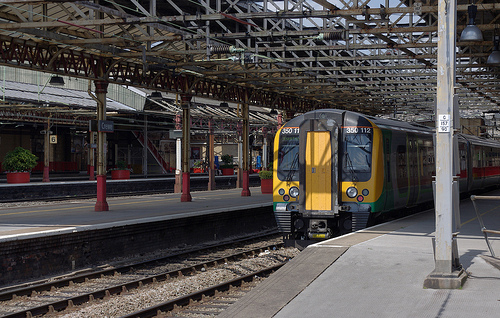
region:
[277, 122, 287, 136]
The number 3 in white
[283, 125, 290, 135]
the number 5 in white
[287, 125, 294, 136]
the number 0 in white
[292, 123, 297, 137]
the number 1 in white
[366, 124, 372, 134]
the number 2 in white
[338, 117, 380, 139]
the number 350 112 in white?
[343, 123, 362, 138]
the number 350 in white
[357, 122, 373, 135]
the number 112 in white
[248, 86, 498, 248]
A big yellow train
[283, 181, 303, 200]
a silver head light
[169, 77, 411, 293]
train with yellow nose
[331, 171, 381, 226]
red and green lights next to headlight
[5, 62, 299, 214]
metal poles with red paint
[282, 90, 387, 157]
numbers on nose of train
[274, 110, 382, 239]
two windows on nose of train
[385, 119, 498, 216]
red stripe on side of train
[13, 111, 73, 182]
sign with number 6 on it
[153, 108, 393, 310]
train on train tracks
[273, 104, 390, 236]
yellow black green on train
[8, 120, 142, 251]
plant on train platform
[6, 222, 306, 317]
two sets of metal train tacks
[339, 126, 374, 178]
a window on a train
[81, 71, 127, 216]
a steel support column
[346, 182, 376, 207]
lights on the front of a train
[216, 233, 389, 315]
a train platform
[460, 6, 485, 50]
an over head light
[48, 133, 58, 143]
the number 6 on a sign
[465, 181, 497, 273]
a metal railing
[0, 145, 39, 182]
a plant in a large pot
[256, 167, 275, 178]
a green plant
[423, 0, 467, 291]
metal pole on train platform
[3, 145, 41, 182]
green plant in red planter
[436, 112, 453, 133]
small white sign on pole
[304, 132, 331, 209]
yellow door on train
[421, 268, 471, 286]
base of pole is gray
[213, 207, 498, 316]
train platform is gray concrete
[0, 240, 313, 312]
train on train track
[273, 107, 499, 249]
train in a train station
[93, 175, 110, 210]
base of post is red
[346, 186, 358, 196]
light on train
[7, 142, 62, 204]
Green plant in red plant holder.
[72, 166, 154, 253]
Bottom of post is red.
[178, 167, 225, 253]
Bottom of post is red.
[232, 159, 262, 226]
Bottom of post is red.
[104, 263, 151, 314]
Gravel in between the tracks.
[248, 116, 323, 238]
Yellow door on train.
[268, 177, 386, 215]
Lights on the back of the train.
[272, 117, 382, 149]
White numbers on the back of the train.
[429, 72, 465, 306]
Gray post near train.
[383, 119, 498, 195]
Train has windows along the side.